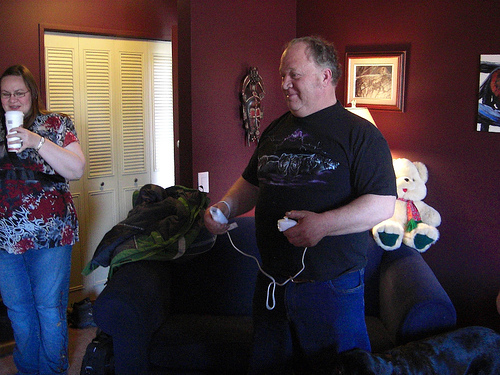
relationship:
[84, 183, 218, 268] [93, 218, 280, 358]
coats on couch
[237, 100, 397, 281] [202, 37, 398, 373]
shirt on a man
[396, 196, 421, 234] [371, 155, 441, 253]
scarf on a bear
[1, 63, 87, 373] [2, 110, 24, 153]
woman holding a coffee cup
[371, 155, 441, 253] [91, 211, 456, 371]
bear on couch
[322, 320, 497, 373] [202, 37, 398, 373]
dog by man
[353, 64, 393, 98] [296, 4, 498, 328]
picture on wall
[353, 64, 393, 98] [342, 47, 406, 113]
picture in frame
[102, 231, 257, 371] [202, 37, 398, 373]
couch by man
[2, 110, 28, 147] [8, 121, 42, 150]
coffee cup in hand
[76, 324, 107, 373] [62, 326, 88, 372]
bag on floor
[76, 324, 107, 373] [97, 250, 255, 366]
bag by couch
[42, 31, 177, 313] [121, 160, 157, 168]
closet doors has slat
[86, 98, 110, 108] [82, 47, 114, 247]
slat on door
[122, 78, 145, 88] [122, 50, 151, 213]
slat on door